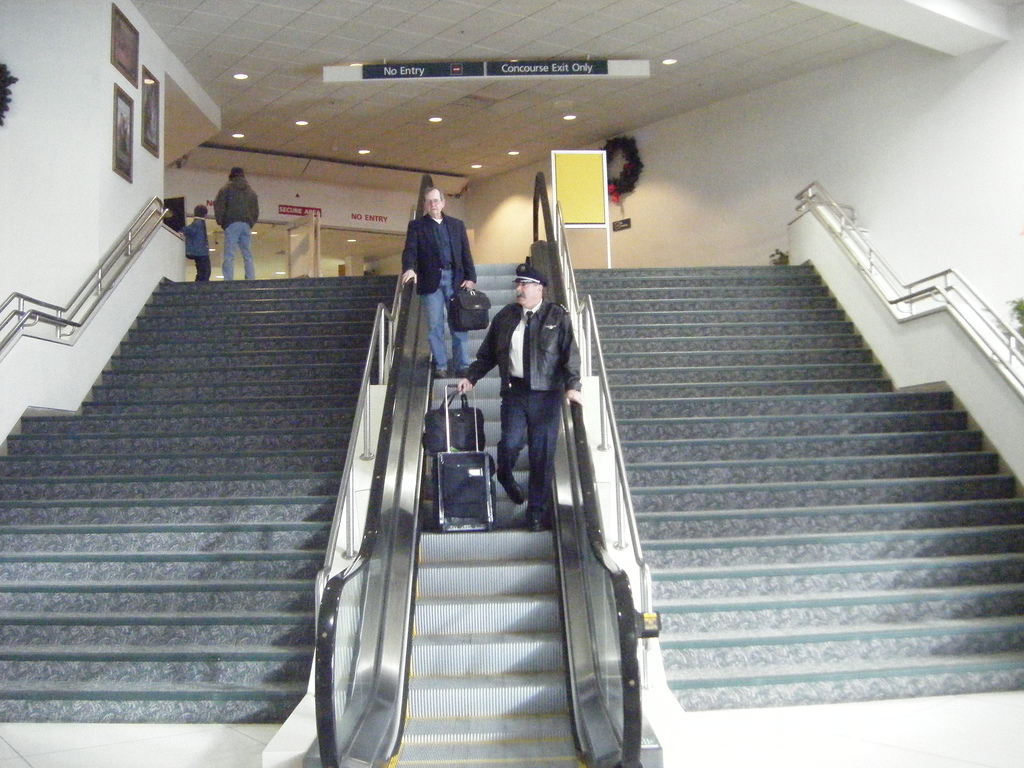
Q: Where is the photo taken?
A: At an airport.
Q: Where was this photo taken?
A: In an airport.